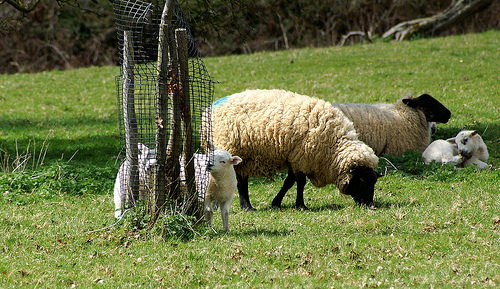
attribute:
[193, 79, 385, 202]
sheep — head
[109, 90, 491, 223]
white cow — black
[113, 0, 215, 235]
wire — wooden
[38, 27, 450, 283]
road — brown